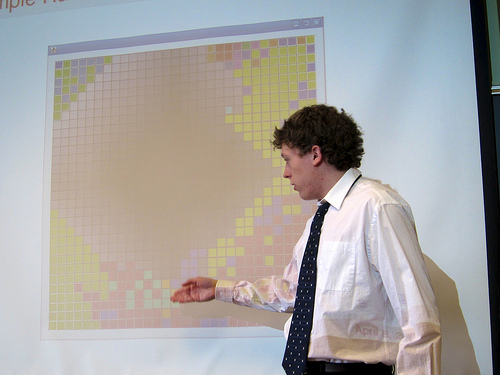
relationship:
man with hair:
[157, 94, 444, 372] [268, 105, 365, 170]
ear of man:
[307, 145, 324, 167] [157, 94, 444, 372]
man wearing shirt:
[157, 94, 444, 372] [210, 162, 450, 372]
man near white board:
[157, 94, 444, 372] [2, 2, 492, 374]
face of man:
[277, 151, 311, 202] [157, 94, 444, 372]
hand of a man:
[165, 274, 218, 306] [157, 94, 444, 372]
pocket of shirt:
[317, 239, 358, 292] [210, 162, 450, 372]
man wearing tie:
[157, 94, 444, 372] [281, 197, 336, 374]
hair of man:
[268, 105, 365, 170] [157, 94, 444, 372]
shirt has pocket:
[210, 162, 450, 372] [317, 239, 358, 292]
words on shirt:
[315, 236, 389, 356] [210, 162, 450, 372]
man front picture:
[157, 94, 444, 372] [59, 69, 288, 321]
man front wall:
[157, 94, 444, 372] [337, 11, 471, 138]